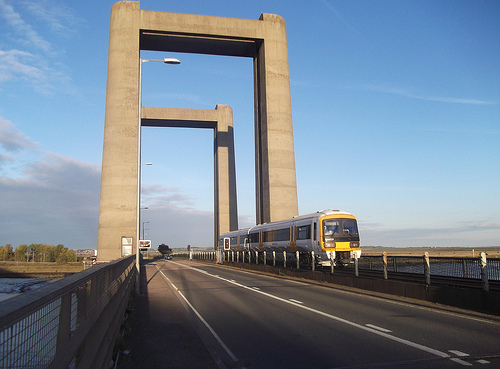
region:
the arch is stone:
[45, 4, 347, 192]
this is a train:
[202, 190, 440, 344]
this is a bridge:
[27, 160, 439, 360]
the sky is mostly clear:
[50, 53, 406, 208]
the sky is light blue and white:
[295, 40, 490, 230]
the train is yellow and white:
[215, 164, 390, 299]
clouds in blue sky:
[2, 1, 497, 252]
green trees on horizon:
[0, 243, 77, 263]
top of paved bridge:
[0, 0, 496, 367]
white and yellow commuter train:
[219, 208, 360, 270]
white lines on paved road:
[157, 256, 487, 366]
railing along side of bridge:
[2, 256, 135, 366]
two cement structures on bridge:
[98, 1, 297, 256]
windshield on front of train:
[321, 212, 361, 249]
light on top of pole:
[137, 57, 182, 238]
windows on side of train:
[220, 224, 314, 244]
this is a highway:
[34, 11, 412, 293]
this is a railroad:
[90, 117, 434, 367]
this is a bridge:
[48, 127, 270, 275]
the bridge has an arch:
[50, 7, 390, 261]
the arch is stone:
[65, 78, 183, 225]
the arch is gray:
[62, 38, 189, 192]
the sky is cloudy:
[21, 107, 143, 294]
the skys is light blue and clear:
[8, 47, 262, 281]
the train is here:
[248, 205, 440, 292]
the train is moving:
[320, 167, 431, 337]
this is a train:
[183, 197, 389, 289]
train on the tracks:
[176, 170, 433, 306]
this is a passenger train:
[187, 201, 394, 260]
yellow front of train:
[309, 209, 376, 256]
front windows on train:
[318, 212, 362, 242]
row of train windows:
[231, 218, 333, 251]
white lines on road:
[190, 257, 415, 359]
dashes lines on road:
[232, 267, 409, 367]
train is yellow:
[220, 210, 361, 265]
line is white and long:
[166, 256, 471, 361]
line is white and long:
[150, 251, 235, 356]